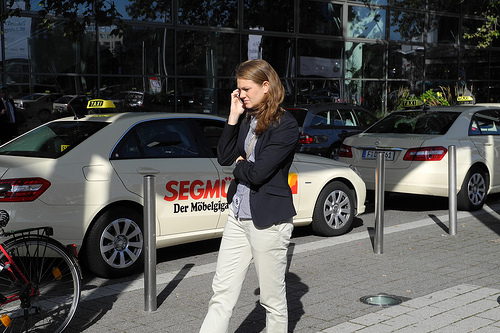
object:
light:
[361, 292, 400, 307]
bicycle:
[0, 209, 85, 332]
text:
[162, 179, 230, 203]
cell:
[237, 92, 244, 104]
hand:
[230, 87, 246, 117]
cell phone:
[237, 93, 244, 104]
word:
[171, 200, 190, 214]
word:
[188, 200, 230, 215]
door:
[109, 118, 220, 236]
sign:
[457, 97, 470, 101]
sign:
[88, 101, 103, 107]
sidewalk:
[8, 207, 500, 333]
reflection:
[0, 1, 499, 148]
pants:
[198, 203, 294, 332]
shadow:
[236, 272, 308, 333]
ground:
[0, 196, 499, 331]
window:
[31, 12, 98, 77]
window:
[95, 20, 146, 76]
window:
[386, 40, 427, 81]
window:
[288, 33, 344, 78]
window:
[166, 27, 208, 83]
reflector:
[52, 268, 64, 281]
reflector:
[2, 314, 12, 327]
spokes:
[2, 242, 83, 333]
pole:
[143, 175, 159, 312]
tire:
[0, 233, 83, 332]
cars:
[337, 96, 500, 212]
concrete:
[73, 202, 498, 329]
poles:
[447, 145, 458, 236]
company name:
[163, 176, 235, 214]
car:
[285, 104, 378, 156]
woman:
[195, 59, 297, 333]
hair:
[235, 58, 285, 134]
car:
[2, 99, 367, 278]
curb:
[0, 203, 496, 318]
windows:
[0, 15, 76, 86]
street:
[0, 0, 500, 333]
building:
[0, 1, 500, 115]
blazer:
[217, 109, 298, 230]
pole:
[372, 153, 386, 254]